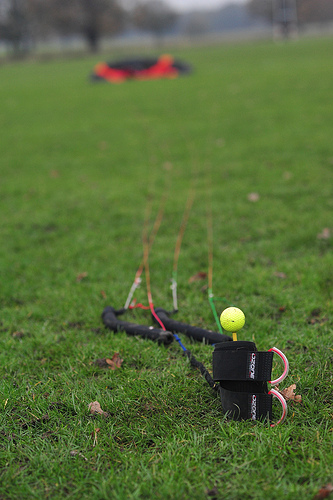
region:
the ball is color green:
[217, 301, 249, 334]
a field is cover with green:
[0, 44, 326, 492]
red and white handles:
[267, 341, 291, 436]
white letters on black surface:
[245, 348, 261, 420]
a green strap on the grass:
[203, 276, 219, 328]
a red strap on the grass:
[142, 286, 163, 329]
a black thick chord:
[87, 277, 221, 357]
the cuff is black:
[202, 302, 273, 427]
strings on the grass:
[120, 72, 219, 307]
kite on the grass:
[60, 15, 238, 149]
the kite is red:
[66, 38, 199, 100]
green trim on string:
[196, 276, 229, 340]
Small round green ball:
[216, 305, 247, 332]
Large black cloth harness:
[207, 341, 277, 424]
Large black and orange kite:
[85, 52, 196, 85]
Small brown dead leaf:
[100, 354, 124, 371]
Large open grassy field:
[0, 35, 332, 496]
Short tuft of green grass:
[133, 445, 187, 477]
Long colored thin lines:
[116, 83, 223, 335]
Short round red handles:
[271, 346, 288, 385]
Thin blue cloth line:
[170, 330, 184, 357]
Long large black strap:
[102, 307, 171, 347]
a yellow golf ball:
[220, 306, 246, 331]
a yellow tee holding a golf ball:
[230, 332, 239, 341]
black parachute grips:
[212, 339, 285, 428]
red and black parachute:
[86, 54, 192, 81]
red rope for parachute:
[123, 263, 167, 330]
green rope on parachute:
[169, 268, 225, 335]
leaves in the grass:
[84, 353, 127, 412]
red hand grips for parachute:
[268, 345, 287, 428]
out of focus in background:
[0, 0, 332, 61]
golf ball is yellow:
[215, 299, 253, 338]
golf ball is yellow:
[216, 301, 245, 334]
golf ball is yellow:
[215, 304, 249, 338]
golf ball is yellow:
[215, 301, 245, 338]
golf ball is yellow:
[212, 304, 248, 327]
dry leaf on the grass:
[265, 373, 304, 420]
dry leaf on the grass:
[274, 376, 301, 416]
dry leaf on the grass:
[274, 382, 318, 414]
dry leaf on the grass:
[273, 380, 307, 415]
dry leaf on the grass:
[268, 375, 310, 409]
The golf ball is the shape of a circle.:
[214, 307, 263, 339]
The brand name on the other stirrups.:
[249, 348, 268, 383]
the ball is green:
[215, 300, 249, 335]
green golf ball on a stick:
[219, 305, 246, 331]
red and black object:
[87, 54, 194, 83]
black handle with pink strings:
[211, 339, 289, 429]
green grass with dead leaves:
[0, 37, 331, 498]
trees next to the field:
[0, 1, 332, 59]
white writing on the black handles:
[248, 352, 258, 422]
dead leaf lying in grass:
[84, 397, 108, 417]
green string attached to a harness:
[207, 287, 224, 332]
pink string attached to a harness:
[146, 290, 167, 332]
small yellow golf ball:
[220, 306, 245, 332]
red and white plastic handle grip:
[266, 345, 289, 384]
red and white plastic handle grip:
[267, 386, 286, 426]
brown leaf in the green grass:
[103, 349, 121, 368]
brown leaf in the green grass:
[187, 271, 206, 281]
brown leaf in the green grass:
[87, 401, 103, 415]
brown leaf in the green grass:
[274, 384, 303, 403]